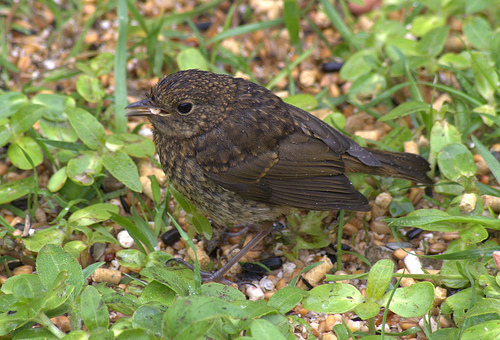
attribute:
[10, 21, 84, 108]
rocks — white, black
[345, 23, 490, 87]
grass — small, green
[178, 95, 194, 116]
eye — black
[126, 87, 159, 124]
beak — black, open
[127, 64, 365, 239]
bird — brown, standing, black, small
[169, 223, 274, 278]
legs — skinny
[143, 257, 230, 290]
feet — long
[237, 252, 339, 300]
seed — cylindrical, black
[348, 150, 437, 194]
tail — brown, black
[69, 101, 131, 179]
leaves — green, wet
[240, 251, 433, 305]
food — white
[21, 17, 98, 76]
debris — orange